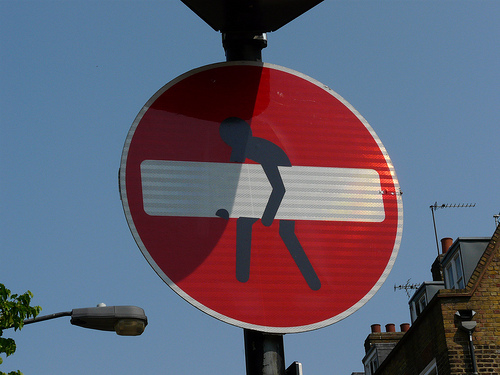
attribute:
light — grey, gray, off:
[1, 301, 148, 337]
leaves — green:
[1, 288, 41, 332]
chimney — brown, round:
[440, 237, 452, 254]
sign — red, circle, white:
[118, 58, 406, 334]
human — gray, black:
[216, 117, 322, 290]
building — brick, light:
[371, 220, 499, 374]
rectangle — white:
[139, 158, 386, 223]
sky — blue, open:
[1, 0, 498, 374]